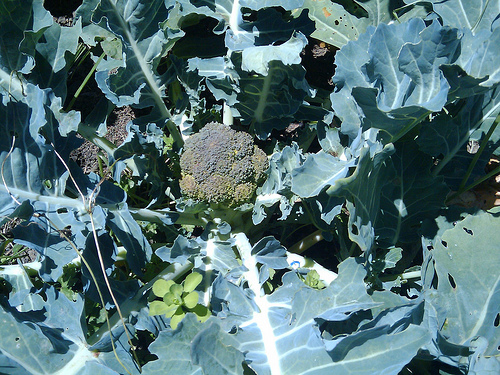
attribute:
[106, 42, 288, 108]
leaves — green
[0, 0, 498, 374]
leaves — green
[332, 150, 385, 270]
leaves — green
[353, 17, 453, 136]
leaves — green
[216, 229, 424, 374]
leaves — green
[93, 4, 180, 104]
leaves — green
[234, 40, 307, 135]
leaves — green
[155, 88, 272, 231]
broccoli. — green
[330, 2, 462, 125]
leaf — green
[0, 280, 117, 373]
leaves — green